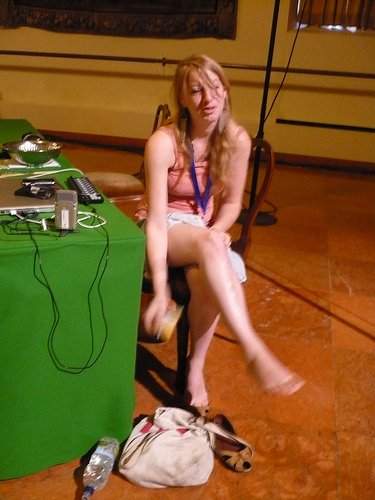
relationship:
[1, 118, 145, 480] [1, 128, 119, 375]
table has items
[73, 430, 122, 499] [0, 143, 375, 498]
bottle on floor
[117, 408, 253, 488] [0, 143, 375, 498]
bag on floor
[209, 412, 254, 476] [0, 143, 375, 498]
shoe on floor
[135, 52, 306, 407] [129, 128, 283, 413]
woman on chair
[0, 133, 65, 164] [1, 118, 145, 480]
bowl on table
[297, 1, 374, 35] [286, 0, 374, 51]
curtain on window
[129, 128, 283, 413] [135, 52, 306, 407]
chair next to woman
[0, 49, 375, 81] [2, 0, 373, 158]
bar against wall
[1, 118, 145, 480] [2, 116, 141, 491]
table has cloth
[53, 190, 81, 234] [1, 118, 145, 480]
speaker on table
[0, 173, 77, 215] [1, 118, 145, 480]
laptop on table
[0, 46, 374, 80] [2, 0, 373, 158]
rail along wall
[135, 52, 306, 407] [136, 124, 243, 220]
woman wearing tank top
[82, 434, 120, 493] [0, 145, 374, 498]
bottle shown on ground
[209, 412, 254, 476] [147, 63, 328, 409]
shoe of person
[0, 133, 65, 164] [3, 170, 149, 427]
bowl on table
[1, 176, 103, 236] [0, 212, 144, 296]
devices are on table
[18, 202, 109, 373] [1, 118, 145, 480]
cable hanging from table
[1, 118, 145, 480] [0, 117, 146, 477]
table covered in material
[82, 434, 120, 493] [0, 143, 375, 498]
bottle on floor